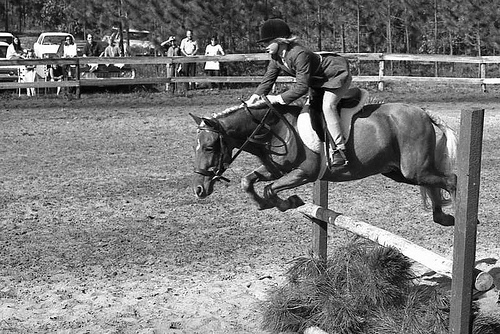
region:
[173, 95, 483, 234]
horse jumping over fence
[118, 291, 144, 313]
patch of grass and dirt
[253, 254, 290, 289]
patch of grass and dirt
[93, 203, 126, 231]
patch of grass and dirt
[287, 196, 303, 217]
hoof of the horse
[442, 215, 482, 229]
hoof of the horse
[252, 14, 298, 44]
helmet on the rider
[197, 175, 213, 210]
nose of the horse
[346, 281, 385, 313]
patch of hay under fence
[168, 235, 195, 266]
patch of dirt and grass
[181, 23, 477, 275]
a horse jumping over a fence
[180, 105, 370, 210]
a horse wearing a reign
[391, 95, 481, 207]
a horses blonde pony tail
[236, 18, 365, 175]
an equestrian riding horseback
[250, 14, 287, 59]
a girl wearing an equestrian hat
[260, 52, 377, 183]
the body of an equestrian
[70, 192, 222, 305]
a large field of dirt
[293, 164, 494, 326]
a large wooden post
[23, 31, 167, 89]
people who are watching the horse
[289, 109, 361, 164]
a white saddle for sitting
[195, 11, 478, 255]
girl riding brown horse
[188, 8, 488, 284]
girl jumping horse over rail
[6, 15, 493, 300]
people watching equestrian show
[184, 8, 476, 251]
horse jumping over piece of wood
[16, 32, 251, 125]
horizontal wooden fence around corral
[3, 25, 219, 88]
people standing in front of parked cars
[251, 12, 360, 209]
girl in riding hat and boots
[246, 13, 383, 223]
girl in riding outfoot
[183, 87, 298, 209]
brown horse with white mane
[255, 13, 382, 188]
girl wearing white riding pants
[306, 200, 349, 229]
shadow of the horse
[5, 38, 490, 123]
fence of the ring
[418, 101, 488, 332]
post of the jump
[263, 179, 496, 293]
rail of the jump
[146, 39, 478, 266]
horse jumping the rail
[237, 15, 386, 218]
woman on a horse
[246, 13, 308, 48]
helmet of the rider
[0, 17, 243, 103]
people watching the horse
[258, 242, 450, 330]
bush under the jump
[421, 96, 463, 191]
tail of the horse